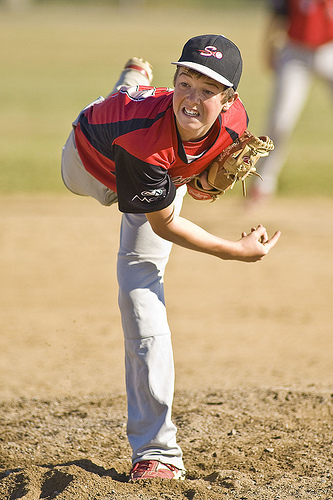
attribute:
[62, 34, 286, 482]
boy — playing, throwing, white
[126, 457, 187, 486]
shoe — red, white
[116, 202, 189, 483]
leg — one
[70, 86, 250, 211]
shirt — red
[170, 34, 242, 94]
cap — black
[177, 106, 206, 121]
mouth — open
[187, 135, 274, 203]
mitt — brown, leather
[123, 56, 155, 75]
spikes — white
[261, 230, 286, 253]
finger — out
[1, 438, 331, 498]
dirt — pile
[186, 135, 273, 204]
glove — tan, brown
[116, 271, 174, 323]
knee — bent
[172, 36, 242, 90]
hat — white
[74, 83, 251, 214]
jersey — black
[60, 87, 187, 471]
pants — colored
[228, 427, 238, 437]
rock — small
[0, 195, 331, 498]
ground — brown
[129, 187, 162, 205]
letters — white